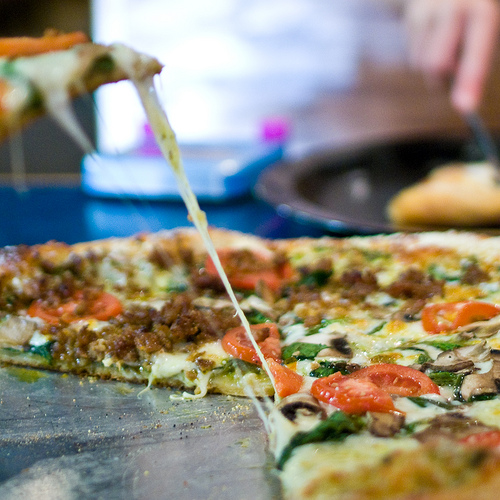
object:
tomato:
[309, 359, 444, 415]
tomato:
[420, 290, 499, 333]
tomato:
[220, 322, 279, 369]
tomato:
[199, 238, 297, 291]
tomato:
[18, 279, 127, 323]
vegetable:
[275, 411, 369, 472]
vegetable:
[427, 368, 464, 388]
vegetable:
[24, 339, 56, 360]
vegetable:
[417, 338, 459, 350]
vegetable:
[278, 340, 326, 363]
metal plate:
[0, 362, 280, 499]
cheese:
[13, 53, 96, 155]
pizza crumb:
[186, 420, 193, 429]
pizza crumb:
[167, 422, 179, 429]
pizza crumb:
[139, 465, 152, 479]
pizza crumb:
[67, 395, 82, 405]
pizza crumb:
[226, 402, 238, 417]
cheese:
[132, 75, 281, 400]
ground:
[305, 50, 499, 163]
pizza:
[0, 26, 163, 129]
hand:
[404, 0, 499, 111]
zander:
[0, 53, 497, 374]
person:
[402, 1, 498, 115]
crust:
[29, 229, 499, 265]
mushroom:
[276, 392, 328, 420]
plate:
[249, 127, 499, 242]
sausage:
[55, 297, 242, 359]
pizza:
[1, 225, 500, 500]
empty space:
[4, 375, 270, 497]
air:
[1, 3, 498, 179]